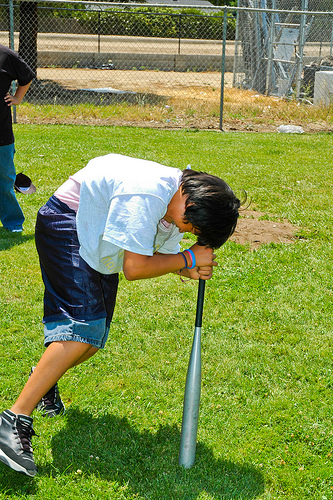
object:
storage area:
[233, 0, 333, 109]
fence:
[0, 0, 332, 132]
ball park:
[1, 122, 332, 498]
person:
[0, 41, 36, 234]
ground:
[14, 87, 333, 127]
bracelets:
[184, 249, 196, 270]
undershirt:
[53, 165, 87, 214]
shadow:
[37, 405, 264, 500]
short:
[34, 195, 118, 349]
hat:
[14, 171, 36, 195]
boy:
[0, 153, 251, 479]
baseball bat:
[177, 278, 205, 470]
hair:
[179, 168, 253, 250]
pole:
[97, 9, 100, 51]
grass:
[1, 121, 332, 498]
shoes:
[0, 408, 36, 479]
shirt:
[75, 153, 186, 276]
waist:
[45, 195, 76, 222]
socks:
[5, 410, 33, 438]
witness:
[0, 43, 35, 233]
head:
[164, 167, 240, 249]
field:
[0, 126, 333, 500]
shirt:
[0, 44, 36, 146]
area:
[232, 0, 333, 107]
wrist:
[178, 248, 192, 271]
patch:
[277, 124, 304, 134]